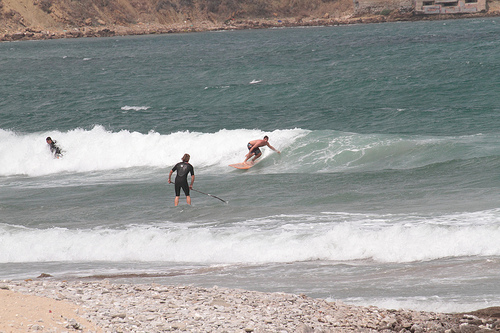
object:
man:
[244, 136, 276, 161]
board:
[230, 160, 258, 172]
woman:
[162, 157, 204, 206]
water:
[1, 20, 500, 321]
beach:
[0, 253, 500, 333]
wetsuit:
[166, 164, 194, 197]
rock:
[0, 280, 500, 331]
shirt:
[43, 142, 61, 154]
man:
[163, 152, 198, 211]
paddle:
[170, 181, 221, 201]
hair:
[183, 152, 191, 162]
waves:
[0, 114, 500, 177]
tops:
[0, 125, 324, 142]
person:
[42, 136, 67, 155]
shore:
[0, 279, 495, 330]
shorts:
[246, 142, 259, 160]